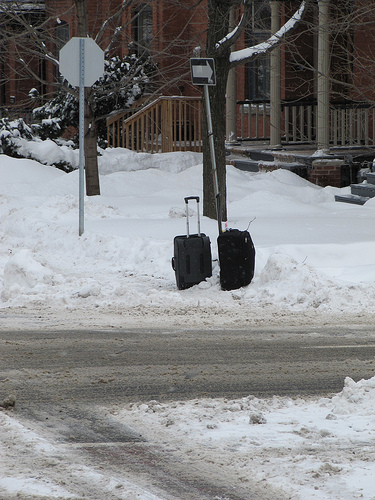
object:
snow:
[16, 147, 366, 322]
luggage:
[175, 191, 212, 294]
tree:
[257, 1, 374, 223]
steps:
[108, 80, 238, 166]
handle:
[183, 193, 203, 233]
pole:
[203, 85, 227, 225]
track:
[4, 322, 375, 499]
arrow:
[189, 61, 212, 84]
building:
[2, 3, 374, 184]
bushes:
[5, 11, 148, 152]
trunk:
[84, 115, 104, 198]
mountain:
[241, 190, 298, 211]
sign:
[58, 33, 105, 234]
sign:
[190, 55, 216, 86]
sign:
[181, 51, 234, 233]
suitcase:
[215, 192, 256, 291]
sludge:
[13, 291, 365, 336]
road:
[2, 268, 367, 409]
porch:
[116, 95, 374, 165]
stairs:
[335, 155, 375, 206]